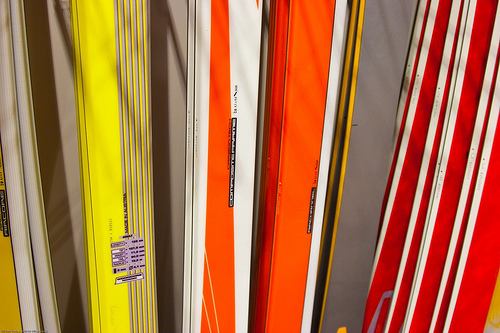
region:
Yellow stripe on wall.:
[82, 82, 127, 212]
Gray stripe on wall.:
[156, 87, 186, 201]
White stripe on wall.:
[193, 142, 205, 204]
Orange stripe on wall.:
[209, 159, 231, 267]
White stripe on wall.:
[233, 142, 254, 219]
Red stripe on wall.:
[267, 130, 279, 187]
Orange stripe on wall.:
[281, 144, 310, 237]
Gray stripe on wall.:
[349, 135, 366, 255]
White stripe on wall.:
[414, 160, 421, 209]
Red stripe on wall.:
[476, 243, 484, 298]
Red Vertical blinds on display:
[348, 0, 494, 327]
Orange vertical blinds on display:
[177, 0, 344, 330]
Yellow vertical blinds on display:
[65, 5, 155, 330]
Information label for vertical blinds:
[110, 230, 145, 280]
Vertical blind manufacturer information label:
[302, 180, 317, 240]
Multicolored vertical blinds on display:
[6, 4, 488, 331]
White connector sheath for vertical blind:
[428, 4, 490, 331]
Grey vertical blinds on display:
[314, 4, 419, 331]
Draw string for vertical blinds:
[186, 243, 221, 331]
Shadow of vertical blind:
[148, 1, 188, 331]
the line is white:
[458, 102, 479, 257]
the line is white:
[430, 106, 449, 320]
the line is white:
[402, 100, 478, 302]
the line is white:
[378, 130, 453, 308]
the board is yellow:
[68, 8, 167, 323]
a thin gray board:
[335, 39, 395, 317]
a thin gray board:
[365, 105, 406, 315]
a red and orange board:
[182, 49, 269, 263]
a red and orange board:
[198, 5, 246, 327]